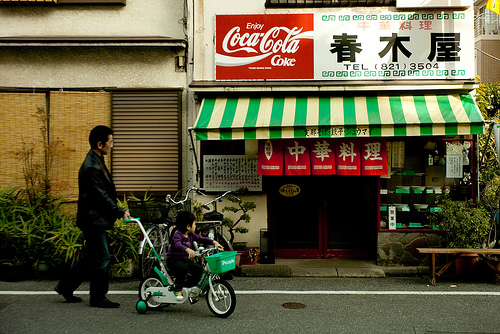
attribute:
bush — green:
[10, 194, 75, 244]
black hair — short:
[55, 113, 149, 164]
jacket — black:
[69, 147, 124, 239]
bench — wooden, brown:
[416, 242, 498, 284]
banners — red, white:
[254, 138, 392, 178]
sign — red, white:
[212, 11, 317, 81]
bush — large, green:
[388, 160, 488, 320]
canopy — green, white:
[288, 91, 348, 122]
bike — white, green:
[135, 189, 283, 324]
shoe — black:
[49, 272, 83, 317]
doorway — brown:
[271, 173, 378, 262]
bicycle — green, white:
[122, 218, 239, 315]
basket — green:
[207, 245, 240, 281]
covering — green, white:
[173, 68, 481, 143]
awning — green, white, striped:
[189, 98, 485, 138]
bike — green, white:
[130, 220, 240, 310]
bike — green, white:
[140, 245, 239, 317]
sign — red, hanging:
[247, 137, 396, 182]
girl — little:
[167, 204, 227, 258]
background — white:
[199, 5, 477, 77]